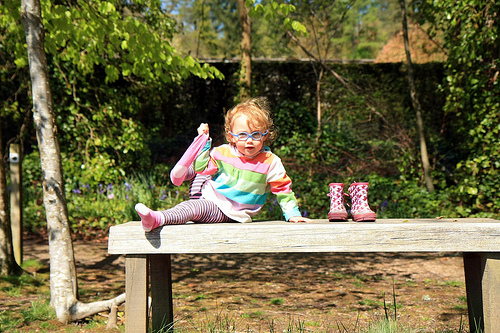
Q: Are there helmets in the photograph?
A: No, there are no helmets.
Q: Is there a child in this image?
A: Yes, there is a child.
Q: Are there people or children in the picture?
A: Yes, there is a child.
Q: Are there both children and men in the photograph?
A: No, there is a child but no men.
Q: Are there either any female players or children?
A: Yes, there is a female child.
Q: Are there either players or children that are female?
A: Yes, the child is female.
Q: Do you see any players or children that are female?
A: Yes, the child is female.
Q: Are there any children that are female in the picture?
A: Yes, there is a female child.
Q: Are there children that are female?
A: Yes, there is a child that is female.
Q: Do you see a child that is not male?
A: Yes, there is a female child.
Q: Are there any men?
A: No, there are no men.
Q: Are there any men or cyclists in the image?
A: No, there are no men or cyclists.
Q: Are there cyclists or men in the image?
A: No, there are no men or cyclists.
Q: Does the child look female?
A: Yes, the child is female.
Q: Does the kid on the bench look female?
A: Yes, the child is female.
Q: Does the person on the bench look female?
A: Yes, the child is female.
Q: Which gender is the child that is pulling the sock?
A: The child is female.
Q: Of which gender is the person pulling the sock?
A: The child is female.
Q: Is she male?
A: No, the kid is female.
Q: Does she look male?
A: No, the child is female.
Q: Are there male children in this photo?
A: No, there is a child but she is female.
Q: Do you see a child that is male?
A: No, there is a child but she is female.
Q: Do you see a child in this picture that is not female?
A: No, there is a child but she is female.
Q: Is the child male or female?
A: The child is female.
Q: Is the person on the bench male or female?
A: The child is female.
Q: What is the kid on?
A: The kid is on the bench.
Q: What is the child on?
A: The kid is on the bench.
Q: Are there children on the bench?
A: Yes, there is a child on the bench.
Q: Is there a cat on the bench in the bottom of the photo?
A: No, there is a child on the bench.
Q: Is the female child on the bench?
A: Yes, the kid is on the bench.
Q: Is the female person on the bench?
A: Yes, the kid is on the bench.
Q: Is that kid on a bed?
A: No, the kid is on the bench.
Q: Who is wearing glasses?
A: The child is wearing glasses.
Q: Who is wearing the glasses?
A: The child is wearing glasses.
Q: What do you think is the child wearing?
A: The child is wearing glasses.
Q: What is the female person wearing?
A: The child is wearing glasses.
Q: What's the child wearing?
A: The child is wearing glasses.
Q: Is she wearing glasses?
A: Yes, the kid is wearing glasses.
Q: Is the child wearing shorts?
A: No, the child is wearing glasses.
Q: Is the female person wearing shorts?
A: No, the child is wearing glasses.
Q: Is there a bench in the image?
A: Yes, there is a bench.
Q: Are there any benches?
A: Yes, there is a bench.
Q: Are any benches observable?
A: Yes, there is a bench.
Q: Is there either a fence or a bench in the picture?
A: Yes, there is a bench.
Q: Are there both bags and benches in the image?
A: No, there is a bench but no bags.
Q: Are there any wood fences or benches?
A: Yes, there is a wood bench.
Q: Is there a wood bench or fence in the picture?
A: Yes, there is a wood bench.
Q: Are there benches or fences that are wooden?
A: Yes, the bench is wooden.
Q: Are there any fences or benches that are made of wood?
A: Yes, the bench is made of wood.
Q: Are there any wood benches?
A: Yes, there is a wood bench.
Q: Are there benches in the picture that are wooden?
A: Yes, there is a bench that is wooden.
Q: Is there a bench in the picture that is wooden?
A: Yes, there is a bench that is wooden.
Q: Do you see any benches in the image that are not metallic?
A: Yes, there is a wooden bench.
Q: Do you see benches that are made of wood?
A: Yes, there is a bench that is made of wood.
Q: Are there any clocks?
A: No, there are no clocks.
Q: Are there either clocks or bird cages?
A: No, there are no clocks or bird cages.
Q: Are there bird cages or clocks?
A: No, there are no clocks or bird cages.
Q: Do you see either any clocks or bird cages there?
A: No, there are no clocks or bird cages.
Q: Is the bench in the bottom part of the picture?
A: Yes, the bench is in the bottom of the image.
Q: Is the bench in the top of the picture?
A: No, the bench is in the bottom of the image.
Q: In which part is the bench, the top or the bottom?
A: The bench is in the bottom of the image.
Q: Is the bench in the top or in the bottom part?
A: The bench is in the bottom of the image.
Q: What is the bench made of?
A: The bench is made of wood.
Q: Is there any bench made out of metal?
A: No, there is a bench but it is made of wood.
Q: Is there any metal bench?
A: No, there is a bench but it is made of wood.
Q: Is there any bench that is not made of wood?
A: No, there is a bench but it is made of wood.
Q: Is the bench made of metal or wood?
A: The bench is made of wood.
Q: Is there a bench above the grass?
A: Yes, there is a bench above the grass.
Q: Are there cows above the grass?
A: No, there is a bench above the grass.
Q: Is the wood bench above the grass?
A: Yes, the bench is above the grass.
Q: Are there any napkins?
A: No, there are no napkins.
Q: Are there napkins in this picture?
A: No, there are no napkins.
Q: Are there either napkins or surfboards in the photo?
A: No, there are no napkins or surfboards.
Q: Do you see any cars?
A: No, there are no cars.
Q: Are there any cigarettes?
A: No, there are no cigarettes.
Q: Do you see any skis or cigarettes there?
A: No, there are no cigarettes or skis.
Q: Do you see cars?
A: No, there are no cars.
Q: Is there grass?
A: Yes, there is grass.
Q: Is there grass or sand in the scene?
A: Yes, there is grass.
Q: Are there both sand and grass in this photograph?
A: No, there is grass but no sand.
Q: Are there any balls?
A: No, there are no balls.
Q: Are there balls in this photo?
A: No, there are no balls.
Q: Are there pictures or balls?
A: No, there are no balls or pictures.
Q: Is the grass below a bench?
A: Yes, the grass is below a bench.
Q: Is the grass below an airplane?
A: No, the grass is below a bench.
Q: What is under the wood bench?
A: The grass is under the bench.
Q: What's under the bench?
A: The grass is under the bench.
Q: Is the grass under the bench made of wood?
A: Yes, the grass is under the bench.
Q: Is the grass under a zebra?
A: No, the grass is under the bench.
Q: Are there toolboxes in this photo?
A: No, there are no toolboxes.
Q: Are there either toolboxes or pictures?
A: No, there are no toolboxes or pictures.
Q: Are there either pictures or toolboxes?
A: No, there are no toolboxes or pictures.